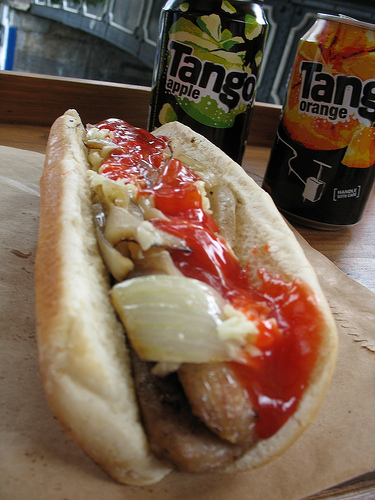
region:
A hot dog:
[49, 106, 317, 463]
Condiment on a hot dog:
[101, 118, 312, 388]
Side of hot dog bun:
[44, 112, 145, 474]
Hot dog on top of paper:
[34, 115, 343, 491]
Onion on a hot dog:
[112, 266, 243, 420]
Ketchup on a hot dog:
[226, 303, 304, 434]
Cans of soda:
[155, 1, 371, 229]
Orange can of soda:
[280, 9, 365, 236]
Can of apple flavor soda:
[155, 4, 260, 158]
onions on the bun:
[41, 93, 320, 362]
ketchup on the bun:
[92, 101, 334, 403]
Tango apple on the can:
[167, 36, 270, 117]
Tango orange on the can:
[297, 57, 372, 132]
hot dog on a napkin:
[7, 99, 370, 497]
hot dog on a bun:
[89, 107, 271, 483]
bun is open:
[2, 98, 373, 463]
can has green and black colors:
[165, 12, 268, 130]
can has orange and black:
[269, 23, 373, 207]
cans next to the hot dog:
[156, 7, 374, 279]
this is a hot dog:
[15, 98, 336, 483]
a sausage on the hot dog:
[112, 242, 254, 476]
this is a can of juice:
[255, 0, 372, 248]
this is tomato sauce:
[238, 287, 313, 432]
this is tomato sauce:
[186, 226, 235, 285]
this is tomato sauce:
[161, 186, 229, 263]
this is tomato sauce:
[119, 143, 191, 208]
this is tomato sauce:
[176, 207, 240, 299]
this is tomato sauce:
[241, 324, 302, 440]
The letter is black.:
[167, 33, 195, 87]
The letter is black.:
[176, 53, 202, 92]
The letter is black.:
[196, 55, 226, 97]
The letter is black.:
[216, 62, 248, 116]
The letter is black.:
[240, 70, 257, 104]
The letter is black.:
[293, 54, 324, 99]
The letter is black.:
[309, 67, 336, 105]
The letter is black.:
[330, 68, 365, 114]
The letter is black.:
[295, 98, 308, 116]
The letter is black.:
[327, 104, 340, 123]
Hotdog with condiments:
[34, 107, 337, 486]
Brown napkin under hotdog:
[0, 146, 373, 494]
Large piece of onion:
[111, 277, 248, 363]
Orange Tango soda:
[261, 19, 372, 231]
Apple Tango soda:
[147, 0, 269, 167]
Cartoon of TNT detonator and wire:
[274, 127, 330, 207]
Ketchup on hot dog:
[98, 118, 323, 437]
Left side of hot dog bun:
[35, 108, 174, 486]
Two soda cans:
[146, 0, 373, 228]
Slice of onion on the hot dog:
[112, 275, 230, 366]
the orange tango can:
[261, 8, 372, 231]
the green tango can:
[142, 4, 248, 174]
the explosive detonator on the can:
[299, 153, 330, 218]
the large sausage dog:
[37, 113, 324, 470]